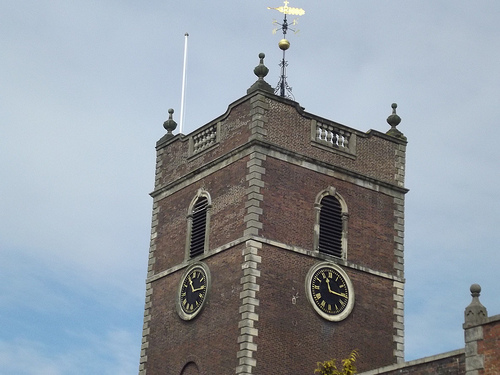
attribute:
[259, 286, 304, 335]
wall — here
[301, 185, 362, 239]
window — here, arched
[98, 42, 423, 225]
castle — here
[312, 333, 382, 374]
plant — here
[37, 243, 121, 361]
sky — here, behind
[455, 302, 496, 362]
pillar — here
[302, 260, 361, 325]
clock — here, round, black, circle, outdoors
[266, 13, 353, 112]
vane — metal, above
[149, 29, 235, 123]
rod — white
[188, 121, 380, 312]
tower — brick, stone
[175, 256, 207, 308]
hand — gold, minute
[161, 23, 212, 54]
bulb — black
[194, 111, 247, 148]
ledge — narrow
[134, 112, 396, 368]
building — brick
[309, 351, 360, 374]
leafs — green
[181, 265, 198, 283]
12 — number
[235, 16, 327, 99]
vain — weather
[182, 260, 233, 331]
face — black